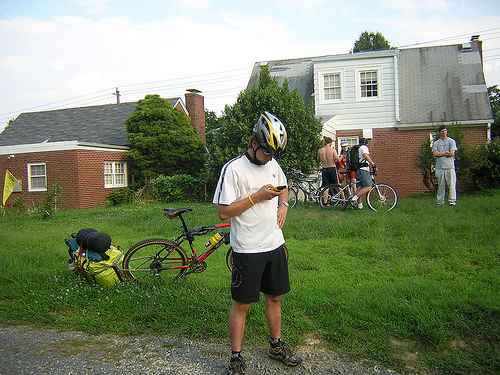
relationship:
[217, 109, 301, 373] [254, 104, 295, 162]
man wears helmet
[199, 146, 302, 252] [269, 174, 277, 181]
shirt has logo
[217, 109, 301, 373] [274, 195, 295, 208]
man wears watch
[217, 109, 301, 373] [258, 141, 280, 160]
man wears glasses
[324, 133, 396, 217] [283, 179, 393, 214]
men have bikes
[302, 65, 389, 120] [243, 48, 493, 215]
window on house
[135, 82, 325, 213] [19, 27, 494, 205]
trees between houses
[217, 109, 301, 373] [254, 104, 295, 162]
man has helmet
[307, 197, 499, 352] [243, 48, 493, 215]
grass in front of house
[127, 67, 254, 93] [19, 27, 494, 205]
power lines behind houses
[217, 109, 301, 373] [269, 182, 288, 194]
man looking at cellphone